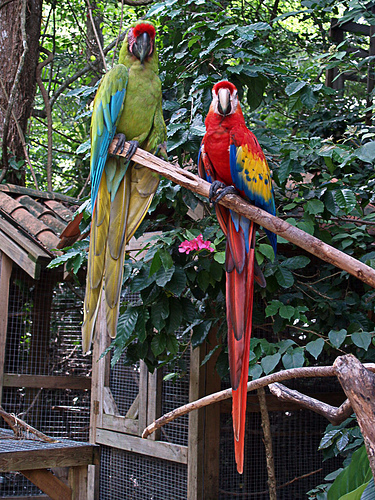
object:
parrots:
[190, 66, 277, 478]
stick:
[97, 131, 373, 314]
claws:
[204, 182, 223, 206]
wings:
[223, 125, 284, 249]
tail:
[204, 225, 262, 483]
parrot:
[62, 12, 165, 381]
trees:
[275, 1, 375, 379]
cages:
[3, 184, 363, 496]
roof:
[2, 188, 147, 284]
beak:
[130, 32, 158, 68]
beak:
[212, 88, 236, 122]